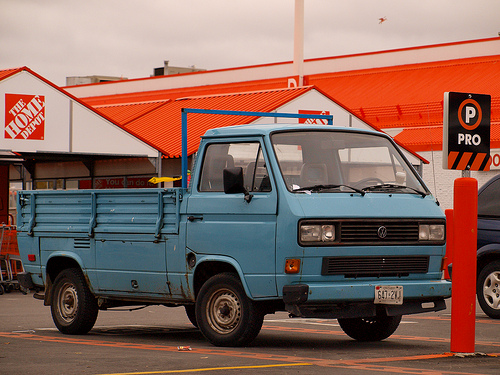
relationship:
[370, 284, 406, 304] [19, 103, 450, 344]
license plate of truck